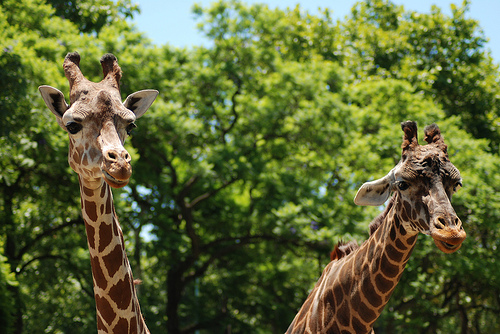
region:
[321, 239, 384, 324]
part of a neck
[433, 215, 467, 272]
part of a mouth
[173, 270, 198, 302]
part of a tree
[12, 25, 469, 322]
giraffe heads against trees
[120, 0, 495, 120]
blue sky above greenish-yellow leaves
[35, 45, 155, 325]
angular head on long neck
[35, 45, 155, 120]
black tipped horns above pointy ears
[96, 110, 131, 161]
slanted nose with dark and oval openings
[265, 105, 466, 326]
neck angled forward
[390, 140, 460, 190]
wrinkled forehead abore black eyes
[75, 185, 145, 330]
tubular neck covered with brown shapes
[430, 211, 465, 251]
four dark ovals arched over open mouth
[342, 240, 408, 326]
brown markings in a vertical row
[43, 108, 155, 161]
giraffe's eyes are black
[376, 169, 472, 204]
giraffe's eyes are black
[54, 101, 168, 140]
giraffe's eyes are black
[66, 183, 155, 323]
giraffe's fur is brown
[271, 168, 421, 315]
giraffe's fur is brown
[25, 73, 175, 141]
giraffe's ears are black and white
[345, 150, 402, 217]
giraffe's ears are black and white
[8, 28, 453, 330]
two brown spotted giraffees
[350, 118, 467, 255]
Giraffe's face among trees.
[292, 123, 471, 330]
Giraffe on right side.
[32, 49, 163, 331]
Giraffe on left side.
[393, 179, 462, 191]
Two eye balls of giraffe.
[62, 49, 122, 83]
Two giraffe horns.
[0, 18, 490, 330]
Green tall tree in background.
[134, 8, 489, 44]
Bright blue cloudless sky through tree.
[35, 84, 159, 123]
Two giraffe ears in alert position.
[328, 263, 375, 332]
Giraffe's brown and tan pattern.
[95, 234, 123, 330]
Giraffe's brown and white pattern.